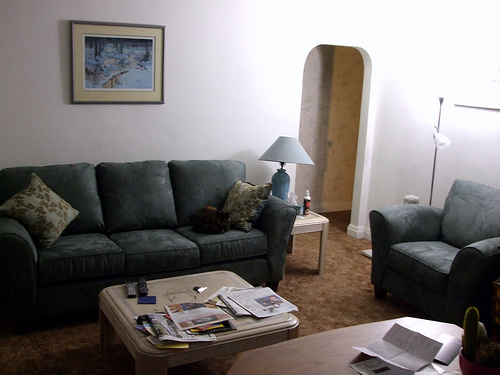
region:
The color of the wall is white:
[179, 15, 284, 129]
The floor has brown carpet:
[296, 262, 393, 337]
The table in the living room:
[88, 265, 300, 372]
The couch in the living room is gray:
[7, 150, 298, 331]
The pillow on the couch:
[3, 175, 85, 251]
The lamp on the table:
[258, 123, 315, 213]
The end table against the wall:
[291, 201, 333, 287]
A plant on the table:
[453, 293, 497, 372]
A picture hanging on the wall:
[61, 12, 182, 117]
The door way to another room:
[288, 29, 375, 254]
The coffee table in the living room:
[101, 262, 303, 374]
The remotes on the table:
[120, 266, 151, 298]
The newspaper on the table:
[131, 275, 296, 352]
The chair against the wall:
[359, 158, 499, 333]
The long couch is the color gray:
[2, 150, 302, 335]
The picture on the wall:
[64, 14, 171, 110]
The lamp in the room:
[421, 87, 451, 209]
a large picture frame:
[65, 18, 170, 106]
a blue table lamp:
[258, 135, 313, 202]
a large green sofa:
[0, 158, 296, 326]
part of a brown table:
[206, 317, 468, 373]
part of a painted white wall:
[173, 26, 302, 121]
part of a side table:
[283, 201, 330, 273]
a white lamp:
[425, 125, 452, 151]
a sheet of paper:
[342, 323, 439, 373]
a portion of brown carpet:
[283, 278, 379, 323]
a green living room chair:
[365, 180, 496, 310]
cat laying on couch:
[191, 198, 232, 245]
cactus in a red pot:
[458, 302, 498, 369]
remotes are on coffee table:
[122, 274, 154, 302]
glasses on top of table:
[161, 283, 199, 303]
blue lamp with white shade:
[257, 125, 308, 209]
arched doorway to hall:
[293, 31, 380, 250]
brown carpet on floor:
[291, 271, 357, 321]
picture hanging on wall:
[67, 20, 162, 104]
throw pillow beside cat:
[214, 181, 276, 232]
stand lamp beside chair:
[427, 91, 453, 218]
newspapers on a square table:
[141, 289, 292, 349]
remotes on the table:
[127, 277, 149, 302]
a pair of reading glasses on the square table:
[167, 288, 197, 304]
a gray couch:
[0, 161, 294, 299]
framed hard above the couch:
[68, 19, 165, 103]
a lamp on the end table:
[259, 135, 312, 202]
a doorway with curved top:
[295, 41, 372, 233]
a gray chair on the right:
[369, 182, 498, 314]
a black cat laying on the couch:
[187, 206, 234, 234]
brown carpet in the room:
[10, 211, 398, 373]